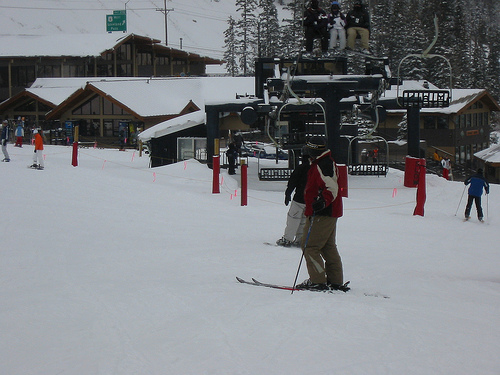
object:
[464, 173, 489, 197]
coat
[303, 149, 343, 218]
coat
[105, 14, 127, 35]
sign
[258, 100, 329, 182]
lift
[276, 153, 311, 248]
person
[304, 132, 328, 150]
hat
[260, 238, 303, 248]
ski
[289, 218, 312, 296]
pole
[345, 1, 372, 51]
people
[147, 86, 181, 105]
snow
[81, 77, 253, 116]
roof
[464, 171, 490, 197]
jacket